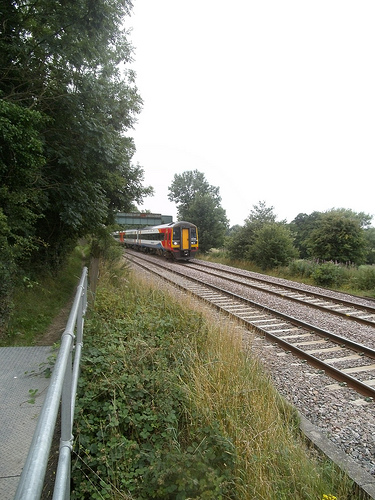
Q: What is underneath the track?
A: Gravel.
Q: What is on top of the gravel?
A: Tracks.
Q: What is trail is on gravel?
A: The tracks.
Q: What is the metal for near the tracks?
A: Railings.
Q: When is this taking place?
A: Daytime.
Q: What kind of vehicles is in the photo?
A: Train.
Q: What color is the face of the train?
A: Orange and yellow.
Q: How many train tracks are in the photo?
A: Two.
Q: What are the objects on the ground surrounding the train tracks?
A: Gravel.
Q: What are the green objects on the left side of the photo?
A: Trees.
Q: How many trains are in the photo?
A: One.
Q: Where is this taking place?
A: Near the train tracks.